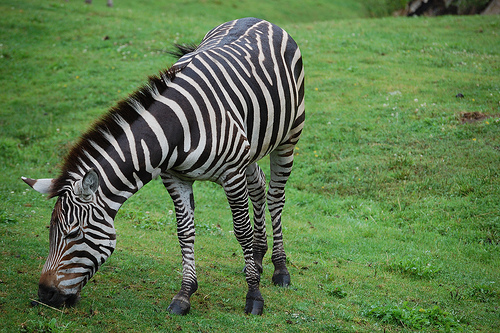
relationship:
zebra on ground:
[21, 17, 306, 315] [0, 0, 499, 331]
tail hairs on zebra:
[170, 36, 198, 57] [21, 17, 306, 315]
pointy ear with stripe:
[70, 170, 99, 202] [135, 90, 183, 160]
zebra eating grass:
[2, 10, 334, 317] [0, 0, 499, 332]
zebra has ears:
[21, 17, 306, 315] [20, 169, 100, 196]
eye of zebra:
[62, 222, 85, 241] [21, 17, 306, 315]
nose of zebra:
[32, 282, 59, 306] [21, 17, 306, 315]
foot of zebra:
[244, 287, 273, 321] [21, 17, 306, 315]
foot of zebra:
[171, 292, 192, 315] [21, 17, 306, 315]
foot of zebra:
[270, 254, 292, 287] [21, 17, 306, 315]